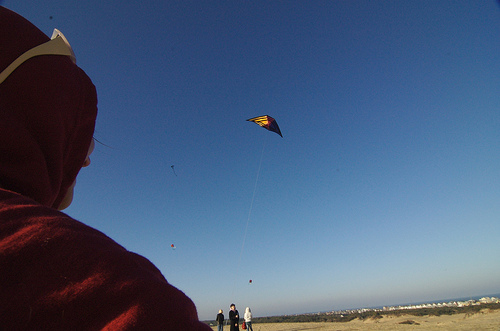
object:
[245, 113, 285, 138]
kite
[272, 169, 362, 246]
air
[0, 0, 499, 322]
sky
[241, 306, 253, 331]
people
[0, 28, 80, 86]
sunglasses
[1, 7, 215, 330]
hoodie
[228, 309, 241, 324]
shirt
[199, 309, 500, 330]
beach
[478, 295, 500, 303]
building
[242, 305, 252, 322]
coat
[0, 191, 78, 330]
back